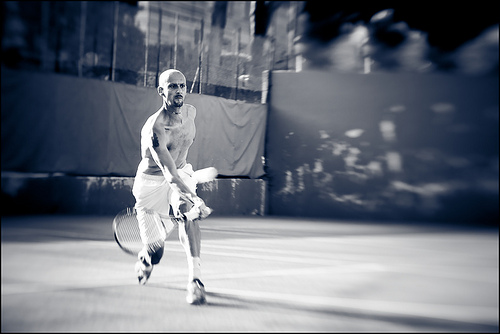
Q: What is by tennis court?
A: Wall.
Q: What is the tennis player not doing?
A: Wearing a shirt.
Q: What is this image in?
A: Black and white.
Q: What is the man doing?
A: Playing tennis.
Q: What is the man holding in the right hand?
A: A tennis racket.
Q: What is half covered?
A: A large fence.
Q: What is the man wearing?
A: Sneakers.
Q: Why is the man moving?
A: To hit a ball.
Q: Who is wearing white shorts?
A: The man.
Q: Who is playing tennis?
A: A man.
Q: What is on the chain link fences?
A: A wind screen.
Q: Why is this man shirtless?
A: It's hot.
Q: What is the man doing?
A: Playing tennis.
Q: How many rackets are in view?
A: 1.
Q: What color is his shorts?
A: White.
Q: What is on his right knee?
A: Brace.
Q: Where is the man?
A: On a tennis court.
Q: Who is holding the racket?
A: The player.